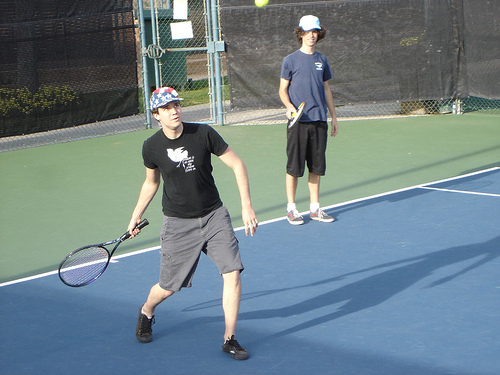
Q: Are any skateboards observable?
A: No, there are no skateboards.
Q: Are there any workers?
A: No, there are no workers.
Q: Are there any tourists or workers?
A: No, there are no workers or tourists.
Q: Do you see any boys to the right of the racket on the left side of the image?
A: Yes, there is a boy to the right of the tennis racket.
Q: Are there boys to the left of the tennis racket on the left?
A: No, the boy is to the right of the racket.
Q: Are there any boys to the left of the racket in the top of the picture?
A: Yes, there is a boy to the left of the tennis racket.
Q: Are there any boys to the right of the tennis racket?
A: No, the boy is to the left of the tennis racket.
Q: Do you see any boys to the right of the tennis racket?
A: No, the boy is to the left of the tennis racket.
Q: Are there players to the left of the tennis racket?
A: No, there is a boy to the left of the tennis racket.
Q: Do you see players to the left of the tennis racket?
A: No, there is a boy to the left of the tennis racket.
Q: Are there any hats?
A: Yes, there is a hat.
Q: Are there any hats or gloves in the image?
A: Yes, there is a hat.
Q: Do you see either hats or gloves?
A: Yes, there is a hat.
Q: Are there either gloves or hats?
A: Yes, there is a hat.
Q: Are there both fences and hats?
A: Yes, there are both a hat and a fence.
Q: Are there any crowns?
A: No, there are no crowns.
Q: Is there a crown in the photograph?
A: No, there are no crowns.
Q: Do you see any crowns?
A: No, there are no crowns.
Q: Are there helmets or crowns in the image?
A: No, there are no crowns or helmets.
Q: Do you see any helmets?
A: No, there are no helmets.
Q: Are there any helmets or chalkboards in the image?
A: No, there are no helmets or chalkboards.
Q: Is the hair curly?
A: Yes, the hair is curly.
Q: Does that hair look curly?
A: Yes, the hair is curly.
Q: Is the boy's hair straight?
A: No, the hair is curly.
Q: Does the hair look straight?
A: No, the hair is curly.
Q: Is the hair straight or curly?
A: The hair is curly.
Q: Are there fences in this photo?
A: Yes, there is a fence.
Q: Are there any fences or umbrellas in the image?
A: Yes, there is a fence.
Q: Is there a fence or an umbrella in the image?
A: Yes, there is a fence.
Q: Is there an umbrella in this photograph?
A: No, there are no umbrellas.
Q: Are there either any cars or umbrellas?
A: No, there are no umbrellas or cars.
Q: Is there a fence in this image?
A: Yes, there is a fence.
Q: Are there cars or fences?
A: Yes, there is a fence.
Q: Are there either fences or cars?
A: Yes, there is a fence.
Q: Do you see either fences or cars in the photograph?
A: Yes, there is a fence.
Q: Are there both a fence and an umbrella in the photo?
A: No, there is a fence but no umbrellas.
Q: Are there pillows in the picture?
A: No, there are no pillows.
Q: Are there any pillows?
A: No, there are no pillows.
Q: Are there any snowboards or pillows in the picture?
A: No, there are no pillows or snowboards.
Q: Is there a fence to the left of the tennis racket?
A: Yes, there is a fence to the left of the racket.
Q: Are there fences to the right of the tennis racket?
A: No, the fence is to the left of the racket.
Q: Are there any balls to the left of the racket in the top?
A: No, there is a fence to the left of the racket.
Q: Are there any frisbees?
A: No, there are no frisbees.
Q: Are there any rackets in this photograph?
A: Yes, there is a racket.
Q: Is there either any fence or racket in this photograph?
A: Yes, there is a racket.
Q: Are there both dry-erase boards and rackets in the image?
A: No, there is a racket but no dry-erase boards.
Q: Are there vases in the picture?
A: No, there are no vases.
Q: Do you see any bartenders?
A: No, there are no bartenders.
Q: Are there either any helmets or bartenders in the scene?
A: No, there are no bartenders or helmets.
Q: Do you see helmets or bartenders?
A: No, there are no bartenders or helmets.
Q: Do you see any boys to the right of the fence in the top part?
A: Yes, there is a boy to the right of the fence.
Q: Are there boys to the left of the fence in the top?
A: No, the boy is to the right of the fence.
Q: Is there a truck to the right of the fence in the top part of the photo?
A: No, there is a boy to the right of the fence.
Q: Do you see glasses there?
A: No, there are no glasses.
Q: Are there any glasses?
A: No, there are no glasses.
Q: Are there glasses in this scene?
A: No, there are no glasses.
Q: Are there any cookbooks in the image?
A: No, there are no cookbooks.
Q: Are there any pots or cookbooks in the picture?
A: No, there are no cookbooks or pots.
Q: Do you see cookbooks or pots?
A: No, there are no cookbooks or pots.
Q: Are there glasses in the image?
A: No, there are no glasses.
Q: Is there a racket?
A: Yes, there is a racket.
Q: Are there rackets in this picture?
A: Yes, there is a racket.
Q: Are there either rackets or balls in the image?
A: Yes, there is a racket.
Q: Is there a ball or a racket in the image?
A: Yes, there is a racket.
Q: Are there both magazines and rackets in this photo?
A: No, there is a racket but no magazines.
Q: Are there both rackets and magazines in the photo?
A: No, there is a racket but no magazines.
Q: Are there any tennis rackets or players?
A: Yes, there is a tennis racket.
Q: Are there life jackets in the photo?
A: No, there are no life jackets.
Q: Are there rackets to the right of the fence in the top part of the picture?
A: Yes, there is a racket to the right of the fence.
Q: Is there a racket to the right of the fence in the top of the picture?
A: Yes, there is a racket to the right of the fence.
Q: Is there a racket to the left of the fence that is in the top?
A: No, the racket is to the right of the fence.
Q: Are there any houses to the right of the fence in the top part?
A: No, there is a racket to the right of the fence.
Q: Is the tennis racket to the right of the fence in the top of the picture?
A: Yes, the tennis racket is to the right of the fence.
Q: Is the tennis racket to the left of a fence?
A: No, the racket is to the right of a fence.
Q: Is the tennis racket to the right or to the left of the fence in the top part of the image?
A: The racket is to the right of the fence.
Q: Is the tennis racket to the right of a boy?
A: Yes, the racket is to the right of a boy.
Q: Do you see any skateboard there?
A: No, there are no skateboards.